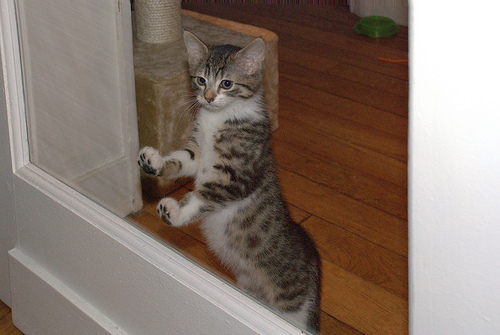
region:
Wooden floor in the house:
[316, 118, 364, 175]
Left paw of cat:
[153, 198, 179, 225]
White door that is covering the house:
[19, 220, 95, 283]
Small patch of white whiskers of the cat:
[182, 103, 192, 118]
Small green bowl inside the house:
[355, 12, 392, 34]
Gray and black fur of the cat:
[262, 212, 292, 249]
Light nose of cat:
[203, 90, 216, 103]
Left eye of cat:
[221, 79, 234, 91]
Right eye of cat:
[194, 74, 209, 87]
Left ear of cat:
[229, 32, 276, 75]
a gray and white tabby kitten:
[133, 24, 340, 328]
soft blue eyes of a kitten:
[178, 60, 247, 99]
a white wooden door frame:
[46, 205, 156, 334]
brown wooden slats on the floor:
[318, 203, 368, 277]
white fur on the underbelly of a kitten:
[205, 222, 250, 276]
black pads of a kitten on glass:
[133, 151, 157, 175]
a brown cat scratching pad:
[136, 1, 191, 141]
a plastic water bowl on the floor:
[348, 8, 393, 46]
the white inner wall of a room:
[49, 13, 131, 165]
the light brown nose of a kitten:
[201, 85, 215, 103]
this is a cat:
[118, 27, 353, 332]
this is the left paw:
[147, 197, 178, 232]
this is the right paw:
[137, 141, 160, 180]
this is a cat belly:
[183, 153, 258, 278]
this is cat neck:
[188, 87, 276, 130]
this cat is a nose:
[202, 84, 219, 105]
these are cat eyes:
[190, 66, 240, 98]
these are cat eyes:
[168, 21, 284, 80]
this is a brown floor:
[328, 155, 357, 191]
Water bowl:
[342, 8, 406, 48]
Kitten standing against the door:
[163, 31, 333, 301]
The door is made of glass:
[39, 32, 179, 197]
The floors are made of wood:
[291, 43, 409, 287]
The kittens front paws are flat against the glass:
[122, 145, 207, 237]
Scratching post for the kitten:
[133, 5, 185, 49]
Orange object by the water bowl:
[371, 45, 410, 82]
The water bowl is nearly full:
[345, 5, 410, 45]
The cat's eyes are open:
[181, 63, 246, 98]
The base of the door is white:
[10, 180, 188, 333]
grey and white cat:
[122, 20, 367, 334]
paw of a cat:
[155, 191, 193, 232]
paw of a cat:
[132, 133, 167, 184]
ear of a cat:
[230, 33, 273, 77]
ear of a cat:
[176, 23, 216, 66]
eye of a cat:
[212, 73, 239, 95]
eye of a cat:
[191, 71, 211, 89]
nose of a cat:
[202, 86, 216, 107]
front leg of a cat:
[145, 136, 255, 238]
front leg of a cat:
[124, 118, 208, 190]